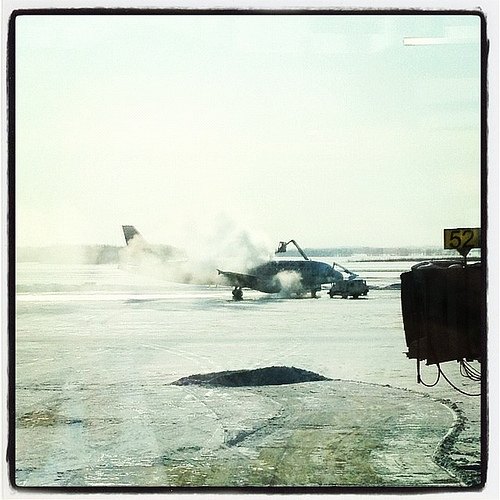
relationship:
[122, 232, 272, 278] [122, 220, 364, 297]
smoke coming out of airplane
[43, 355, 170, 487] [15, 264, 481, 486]
skid marks on pathway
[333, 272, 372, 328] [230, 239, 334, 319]
truck close to airplane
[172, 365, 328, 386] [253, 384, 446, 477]
dirt on pathway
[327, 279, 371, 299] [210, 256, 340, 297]
truck in front of airplane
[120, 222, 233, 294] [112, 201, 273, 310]
wing hidden behind smoke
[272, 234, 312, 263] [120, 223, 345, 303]
crane above airplane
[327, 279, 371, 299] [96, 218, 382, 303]
truck in front of plane'